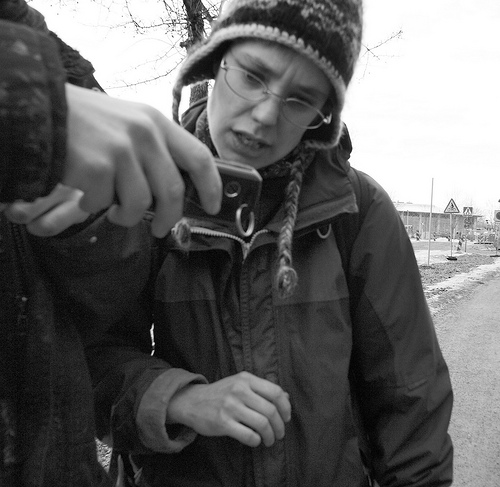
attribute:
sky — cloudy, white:
[405, 22, 498, 126]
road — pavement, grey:
[454, 296, 495, 364]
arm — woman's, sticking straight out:
[113, 335, 303, 466]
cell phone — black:
[223, 157, 264, 241]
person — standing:
[164, 5, 367, 116]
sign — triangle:
[439, 194, 461, 217]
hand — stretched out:
[189, 362, 299, 457]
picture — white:
[6, 5, 484, 478]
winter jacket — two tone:
[273, 188, 450, 470]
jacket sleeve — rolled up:
[103, 343, 214, 458]